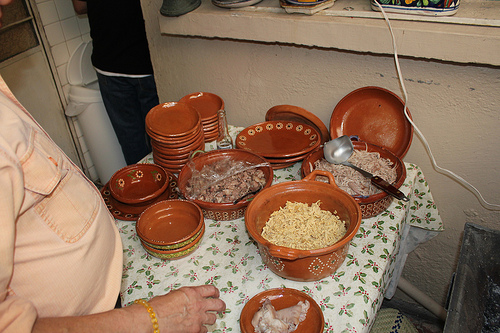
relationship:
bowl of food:
[242, 168, 362, 289] [259, 202, 349, 249]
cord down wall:
[375, 0, 500, 219] [142, 1, 500, 202]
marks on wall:
[401, 76, 481, 96] [142, 1, 500, 202]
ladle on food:
[322, 133, 411, 203] [309, 150, 406, 194]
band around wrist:
[135, 297, 162, 332] [150, 296, 173, 333]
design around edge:
[267, 123, 303, 131] [286, 118, 297, 125]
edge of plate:
[286, 118, 297, 125] [234, 116, 321, 161]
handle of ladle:
[371, 176, 407, 206] [322, 133, 411, 203]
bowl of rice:
[242, 168, 362, 289] [259, 202, 349, 249]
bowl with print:
[106, 165, 170, 203] [129, 170, 146, 182]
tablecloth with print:
[110, 123, 446, 331] [206, 243, 259, 289]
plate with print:
[234, 116, 321, 161] [264, 122, 286, 132]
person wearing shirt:
[1, 71, 223, 332] [0, 76, 120, 331]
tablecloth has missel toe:
[110, 123, 446, 331] [181, 269, 200, 282]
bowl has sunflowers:
[106, 165, 170, 203] [130, 170, 165, 184]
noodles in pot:
[259, 202, 349, 249] [242, 168, 362, 289]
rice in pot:
[259, 202, 349, 249] [242, 168, 362, 289]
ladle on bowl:
[322, 133, 411, 203] [301, 137, 408, 222]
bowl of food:
[301, 137, 408, 222] [309, 150, 406, 194]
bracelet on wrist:
[135, 297, 162, 332] [150, 296, 173, 333]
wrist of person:
[150, 296, 173, 333] [1, 71, 223, 332]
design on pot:
[306, 257, 341, 277] [242, 168, 362, 289]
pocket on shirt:
[9, 126, 104, 243] [0, 76, 120, 331]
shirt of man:
[0, 76, 120, 331] [1, 71, 223, 332]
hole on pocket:
[47, 155, 60, 170] [9, 126, 104, 243]